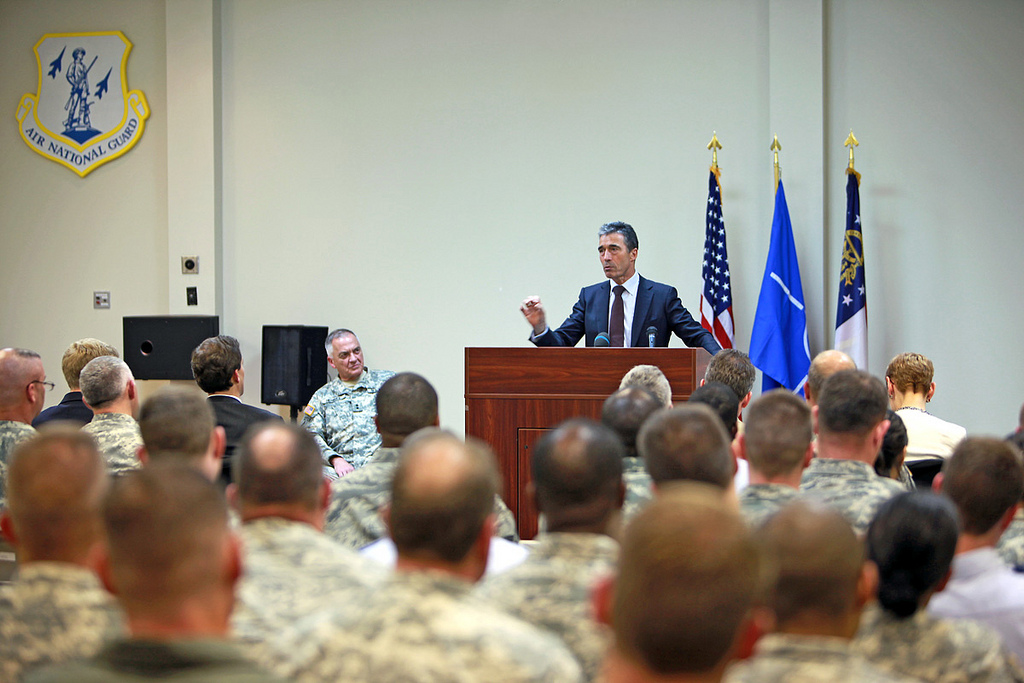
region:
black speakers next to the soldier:
[166, 301, 329, 396]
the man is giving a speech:
[0, 7, 950, 561]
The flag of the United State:
[698, 120, 740, 351]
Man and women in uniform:
[13, 319, 1012, 656]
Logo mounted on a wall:
[13, 15, 154, 192]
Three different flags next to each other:
[676, 113, 898, 398]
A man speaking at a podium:
[511, 194, 717, 363]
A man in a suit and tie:
[508, 189, 696, 346]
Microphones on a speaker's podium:
[587, 319, 667, 354]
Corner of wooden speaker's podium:
[452, 333, 520, 410]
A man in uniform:
[305, 310, 391, 475]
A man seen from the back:
[363, 421, 515, 593]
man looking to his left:
[322, 326, 374, 407]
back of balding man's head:
[237, 415, 323, 515]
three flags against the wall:
[692, 121, 879, 381]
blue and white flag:
[754, 130, 813, 394]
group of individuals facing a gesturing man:
[13, 333, 1020, 679]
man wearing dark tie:
[604, 282, 634, 352]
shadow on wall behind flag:
[869, 172, 901, 351]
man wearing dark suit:
[582, 282, 678, 328]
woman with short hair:
[882, 348, 959, 448]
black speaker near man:
[247, 305, 333, 427]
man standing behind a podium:
[512, 191, 700, 471]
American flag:
[683, 125, 737, 394]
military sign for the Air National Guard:
[15, 21, 149, 177]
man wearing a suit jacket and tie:
[517, 198, 714, 360]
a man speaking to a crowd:
[318, 206, 948, 659]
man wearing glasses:
[3, 343, 61, 421]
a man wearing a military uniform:
[299, 313, 410, 497]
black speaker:
[255, 321, 336, 414]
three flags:
[701, 130, 880, 445]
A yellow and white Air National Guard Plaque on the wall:
[16, 23, 144, 159]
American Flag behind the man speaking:
[693, 127, 722, 321]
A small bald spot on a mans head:
[389, 424, 465, 504]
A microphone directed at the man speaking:
[636, 307, 649, 334]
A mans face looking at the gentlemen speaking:
[324, 320, 364, 372]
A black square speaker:
[115, 311, 191, 363]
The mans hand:
[512, 273, 552, 319]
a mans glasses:
[32, 367, 48, 380]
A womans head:
[877, 337, 923, 392]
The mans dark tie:
[610, 280, 623, 338]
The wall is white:
[298, 23, 549, 196]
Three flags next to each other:
[680, 123, 902, 401]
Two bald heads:
[230, 388, 514, 592]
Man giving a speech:
[522, 197, 711, 393]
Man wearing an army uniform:
[275, 312, 417, 489]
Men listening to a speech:
[9, 232, 1015, 661]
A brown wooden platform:
[452, 326, 717, 524]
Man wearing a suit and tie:
[507, 201, 723, 386]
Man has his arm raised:
[518, 228, 722, 384]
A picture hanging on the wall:
[5, 18, 164, 193]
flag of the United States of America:
[695, 124, 738, 347]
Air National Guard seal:
[13, 21, 157, 176]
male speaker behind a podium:
[468, 217, 715, 541]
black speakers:
[117, 311, 330, 410]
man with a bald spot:
[221, 409, 340, 526]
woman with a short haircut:
[884, 346, 941, 411]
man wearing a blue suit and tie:
[520, 204, 729, 353]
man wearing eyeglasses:
[2, 343, 61, 423]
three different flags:
[694, 130, 875, 378]